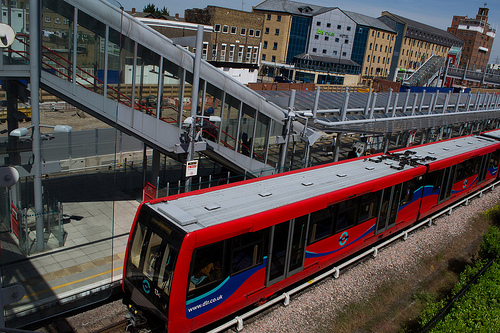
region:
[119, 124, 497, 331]
a red commuter train stopped at the station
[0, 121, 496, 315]
a paved platform at the train station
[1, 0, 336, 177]
a covered staircase behind the train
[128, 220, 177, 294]
front window of the train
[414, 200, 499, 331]
green plants next to the train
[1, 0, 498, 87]
buildings behind the train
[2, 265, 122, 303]
yellow line on the platform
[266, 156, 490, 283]
doors on the side of the train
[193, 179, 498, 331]
a white guard rail next to the train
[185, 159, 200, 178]
a small, white sign below the staircase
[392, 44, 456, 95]
industrial stairway at a distance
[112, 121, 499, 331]
red and blue subway train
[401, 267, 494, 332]
green foilage during the summer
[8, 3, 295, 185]
industrial walkway during the daytime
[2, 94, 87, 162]
two industrial lamps during daylight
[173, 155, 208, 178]
crowd control sign for subway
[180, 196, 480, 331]
safety rail to protect people from subway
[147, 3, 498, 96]
row of old buildings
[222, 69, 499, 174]
depot for modern subway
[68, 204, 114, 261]
outdoor tiles for walkway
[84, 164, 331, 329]
the train is red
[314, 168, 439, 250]
the train is red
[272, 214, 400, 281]
the train is red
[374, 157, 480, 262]
the train is red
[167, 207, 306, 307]
the train is red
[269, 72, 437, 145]
the roof is gray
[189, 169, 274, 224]
the roof is gray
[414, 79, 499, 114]
the roof is gray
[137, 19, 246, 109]
the roof is gray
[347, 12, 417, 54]
the roof is gray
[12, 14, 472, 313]
a train in the city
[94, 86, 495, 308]
the train is red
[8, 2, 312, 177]
stairs next to the train platform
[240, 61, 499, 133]
parts of a train platform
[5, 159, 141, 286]
the train platform is clear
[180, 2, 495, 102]
buildings in the background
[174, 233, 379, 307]
the train is blue and red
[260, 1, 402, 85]
a brown and tan building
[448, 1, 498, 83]
a brown buildiing in the scene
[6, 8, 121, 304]
a glass wall at the train platform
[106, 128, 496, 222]
top of train is gray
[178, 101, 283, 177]
people are walking inside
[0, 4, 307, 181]
the structure is gray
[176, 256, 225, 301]
person driving the train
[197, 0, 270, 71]
the building is brown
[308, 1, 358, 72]
the building is gray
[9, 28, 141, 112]
stair case railing is red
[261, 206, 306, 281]
train doors are black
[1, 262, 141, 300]
yellow line on platform